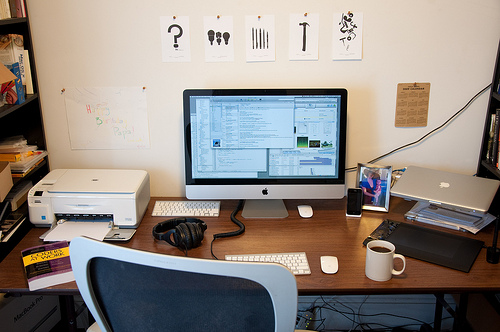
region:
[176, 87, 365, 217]
black and white monitor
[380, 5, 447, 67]
white wall behind monitor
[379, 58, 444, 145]
brown calendar on wall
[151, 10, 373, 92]
pieces of paper on wall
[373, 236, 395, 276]
white mug on desk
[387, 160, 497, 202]
grey and white laptop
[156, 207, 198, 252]
black headphones on desk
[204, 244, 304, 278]
white keyboard on desk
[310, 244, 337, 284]
white mouse on desk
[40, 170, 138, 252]
white printer near monitor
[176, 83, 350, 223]
computer monitor on the desk.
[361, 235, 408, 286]
Coffee cup on the desk.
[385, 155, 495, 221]
laptop on the desk.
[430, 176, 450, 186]
Apple logo on the computer.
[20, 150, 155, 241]
Printer on the desk.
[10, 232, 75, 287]
book on the desk.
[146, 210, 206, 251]
Headphone on the desk.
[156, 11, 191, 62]
Question mark on the paper.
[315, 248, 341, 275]
Mouse on the desk.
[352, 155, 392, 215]
Picture on the desk.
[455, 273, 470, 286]
part of a table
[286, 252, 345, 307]
edge of a table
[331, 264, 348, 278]
part of a mouse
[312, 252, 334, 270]
edge of a plate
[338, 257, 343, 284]
edge of a table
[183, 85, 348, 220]
A monitor on a desk.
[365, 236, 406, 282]
A mug on a desk.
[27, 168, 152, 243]
A printer on a desk.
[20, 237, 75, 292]
A book on a desk.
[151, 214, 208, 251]
Headphones on a desk.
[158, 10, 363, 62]
Paper on a wall.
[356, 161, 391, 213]
A picture on a desk.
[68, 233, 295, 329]
A chair at a desk.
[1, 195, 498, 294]
A brown wood desk.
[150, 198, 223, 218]
A keyboard on a desk.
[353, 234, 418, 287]
The coffee cup is white.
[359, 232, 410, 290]
The coffee cup has a handle.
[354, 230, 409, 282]
The coffee cup is full.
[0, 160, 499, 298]
The coffee cup is sitting on the desk.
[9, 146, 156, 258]
The printer is white.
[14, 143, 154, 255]
The printer has paper in the tray.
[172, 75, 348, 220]
The computer monitor is an Apple brand.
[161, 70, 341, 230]
The computer monitor is on.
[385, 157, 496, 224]
The laptop is an Apple brand.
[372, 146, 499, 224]
The laptop is closed.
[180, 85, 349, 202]
a large flat screen monitor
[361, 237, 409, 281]
a white porcelain coffee cup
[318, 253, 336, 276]
a white plastic computer mouse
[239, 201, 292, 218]
a grey monitor base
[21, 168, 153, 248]
a large white printer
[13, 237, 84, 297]
a black and yellow book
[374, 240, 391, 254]
coffee in a cup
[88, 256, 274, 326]
the black back of a chair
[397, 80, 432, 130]
a note attached to a wall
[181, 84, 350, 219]
Grey and black computer monitor.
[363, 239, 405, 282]
White coffee cup with white handle.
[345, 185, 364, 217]
Black phone on a dock.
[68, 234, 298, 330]
A grey and black desk chair.